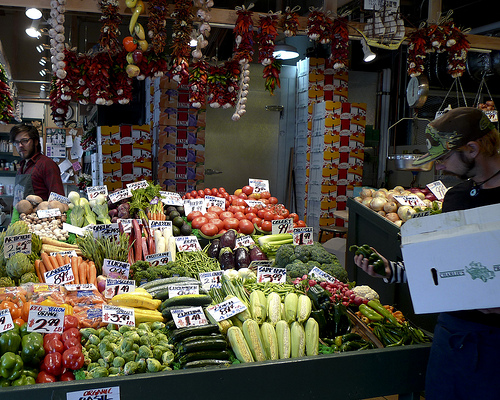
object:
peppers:
[61, 345, 84, 370]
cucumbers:
[182, 339, 228, 354]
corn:
[297, 292, 313, 324]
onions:
[55, 234, 62, 238]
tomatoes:
[191, 216, 209, 229]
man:
[7, 123, 66, 225]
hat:
[408, 105, 497, 168]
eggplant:
[235, 245, 252, 272]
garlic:
[191, 45, 204, 59]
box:
[344, 192, 444, 334]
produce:
[351, 184, 445, 228]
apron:
[7, 169, 37, 227]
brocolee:
[273, 242, 296, 268]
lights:
[357, 26, 377, 64]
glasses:
[11, 136, 32, 146]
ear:
[254, 303, 266, 323]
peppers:
[20, 332, 46, 364]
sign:
[169, 305, 210, 330]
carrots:
[78, 262, 86, 285]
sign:
[41, 263, 75, 287]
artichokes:
[430, 201, 441, 211]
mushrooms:
[16, 199, 35, 216]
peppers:
[348, 243, 388, 277]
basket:
[385, 117, 435, 174]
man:
[352, 105, 500, 400]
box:
[398, 203, 499, 316]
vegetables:
[383, 201, 399, 214]